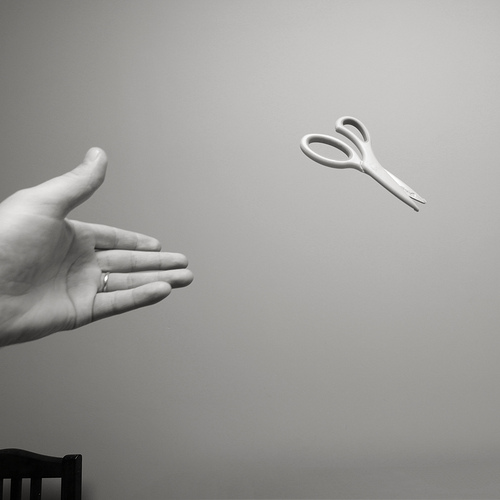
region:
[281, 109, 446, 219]
the scissors are in the air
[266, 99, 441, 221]
the scissors are plastic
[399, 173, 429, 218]
the scissors are slightly open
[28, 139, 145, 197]
the hand has a thumb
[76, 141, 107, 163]
the thumbnail is clean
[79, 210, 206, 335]
the hand has fingers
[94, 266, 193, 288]
the finger has a ring on it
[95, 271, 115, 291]
the ring is gold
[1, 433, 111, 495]
the chair is dark brown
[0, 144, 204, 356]
the hand is open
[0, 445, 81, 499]
back of a chair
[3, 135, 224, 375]
a human hand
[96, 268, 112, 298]
a wedding ring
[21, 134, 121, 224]
the thumb on a left hand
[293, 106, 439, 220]
a pair of scissors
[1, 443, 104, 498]
the back of a wooden chair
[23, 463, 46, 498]
a rung on a wooden chair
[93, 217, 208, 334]
fingers on a human hand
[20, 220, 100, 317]
the palm of a hand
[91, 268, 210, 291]
the ring finger on a human hand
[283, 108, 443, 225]
scissors in the air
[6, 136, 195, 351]
hand with a ring on it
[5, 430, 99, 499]
chair in the corner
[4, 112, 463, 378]
hand throwing scissors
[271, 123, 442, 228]
plastic scissors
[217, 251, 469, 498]
blank wall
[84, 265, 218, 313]
this is a married person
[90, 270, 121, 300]
this is a gold ring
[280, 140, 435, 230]
these are left handed scissors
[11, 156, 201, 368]
this person is left handed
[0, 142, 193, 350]
the left hand reaching out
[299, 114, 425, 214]
the pair of scissors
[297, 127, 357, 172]
the larger hole in the scissors handle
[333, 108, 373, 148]
the smaller hole in the pair of scissors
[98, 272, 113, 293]
the ring on the finger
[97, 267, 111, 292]
the shiny ring on the finger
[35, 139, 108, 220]
the thumb on the hand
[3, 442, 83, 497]
the corner of a chair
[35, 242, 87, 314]
the lines on the hand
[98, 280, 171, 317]
the pinky finger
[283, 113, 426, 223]
small scissors in the air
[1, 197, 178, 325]
palm of a hand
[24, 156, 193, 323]
hand with fingers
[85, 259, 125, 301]
shiny metal ring on finger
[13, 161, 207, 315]
hand wearing a ring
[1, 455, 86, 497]
black seat of a chair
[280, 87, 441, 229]
black and white scissors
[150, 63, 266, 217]
bare white wall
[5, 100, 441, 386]
hand throwing a pair of scissors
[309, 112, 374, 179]
black and white plastic scissors